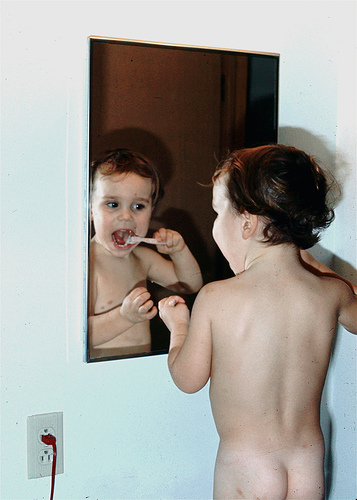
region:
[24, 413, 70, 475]
White plug in the wall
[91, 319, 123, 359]
Reflection in the mirror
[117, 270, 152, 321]
Reflection in the mirror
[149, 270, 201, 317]
Reflection in the mirror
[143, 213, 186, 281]
Reflection in the mirror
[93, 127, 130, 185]
Reflection in the mirror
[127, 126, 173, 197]
Reflection in the mirror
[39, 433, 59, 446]
red cord in socket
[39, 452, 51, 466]
empty socket on wall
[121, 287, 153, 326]
reflection of hand in mirror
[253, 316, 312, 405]
bare back of boy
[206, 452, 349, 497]
bare butt of boy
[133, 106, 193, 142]
reflection of door behind boy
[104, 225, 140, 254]
boys mouth is open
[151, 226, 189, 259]
boy hand on toothbrush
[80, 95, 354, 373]
boy brushing teeth in mirror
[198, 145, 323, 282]
head of a person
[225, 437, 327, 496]
butt of a person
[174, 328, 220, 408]
arm of a person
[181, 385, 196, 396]
elbow of a person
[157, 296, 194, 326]
hand of a person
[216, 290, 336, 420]
back of a person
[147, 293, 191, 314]
fingers of a person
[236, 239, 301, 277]
neck of a person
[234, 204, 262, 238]
ear of a person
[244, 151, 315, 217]
hair of a person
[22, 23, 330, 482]
toddler brushing his teeth naked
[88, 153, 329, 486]
toddler looking at himself in the mirror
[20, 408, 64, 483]
outlet with a red plug in it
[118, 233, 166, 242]
toddler holding toothbrush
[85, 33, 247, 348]
door visible in mirror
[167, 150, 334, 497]
naked toddler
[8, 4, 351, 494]
light blue walls in the bathroom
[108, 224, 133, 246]
toodler with his mouth open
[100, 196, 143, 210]
toddler has brown eyes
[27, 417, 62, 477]
outlet was installed upside down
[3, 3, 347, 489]
white wall with rectangular mirror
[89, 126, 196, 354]
young child brushing teeth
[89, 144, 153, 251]
child looking at own reflection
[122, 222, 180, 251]
fingers curled around end of toothbrush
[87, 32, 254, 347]
dark brown door behind child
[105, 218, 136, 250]
wide mouth showing curve of lower teeth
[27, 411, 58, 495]
red plug and wire in white socket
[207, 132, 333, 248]
dark smooth and curly hair over head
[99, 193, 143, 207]
bright and clear brown eyes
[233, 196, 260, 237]
hair curved over top of ear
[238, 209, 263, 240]
Ear of a boy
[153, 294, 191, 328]
Hand of a boy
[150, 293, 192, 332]
Hand of a boy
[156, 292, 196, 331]
Hand of a boy